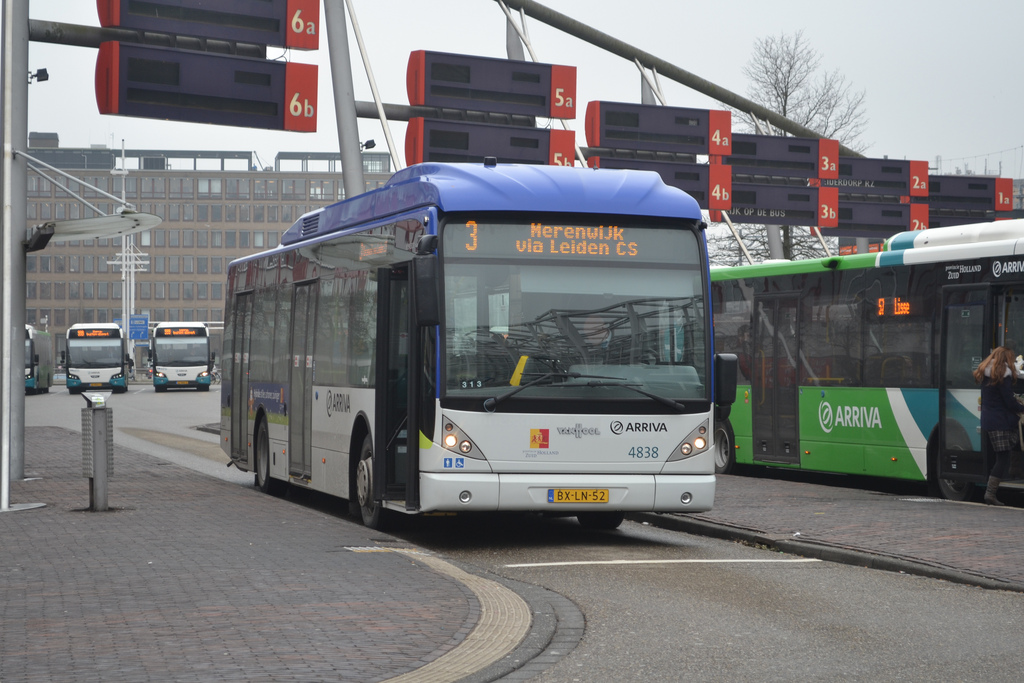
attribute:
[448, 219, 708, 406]
glass — clear, clean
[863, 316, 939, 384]
glass — clean, clear